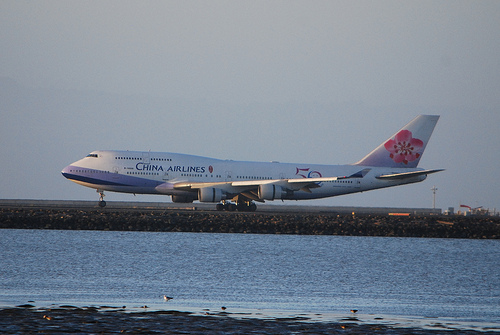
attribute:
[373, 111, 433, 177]
big flower on tail — pink, red,  bright pink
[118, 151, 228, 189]
plane has writing — passenger airplane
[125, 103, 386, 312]
plane has wing — large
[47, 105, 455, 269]
plane on landing are —  of Airplane,  with China Airlines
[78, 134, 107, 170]
cockpit window — plane's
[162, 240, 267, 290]
body of water —  blue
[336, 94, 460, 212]
tail of airplane —  Airplane's,  with flower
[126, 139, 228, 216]
china airline — passenger airplane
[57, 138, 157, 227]
airplane has blue — with blue stripe,  the Front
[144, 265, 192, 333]
small bird in water —  small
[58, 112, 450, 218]
airplanes color —  white